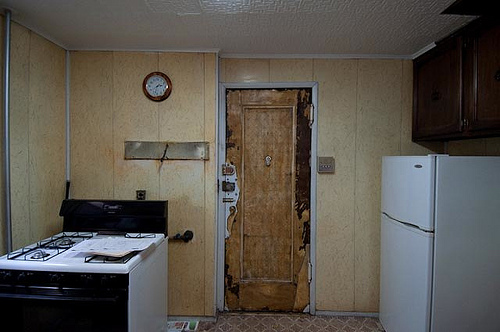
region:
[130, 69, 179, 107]
A clock on the wall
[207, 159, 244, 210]
Three locks on the door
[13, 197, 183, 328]
A stove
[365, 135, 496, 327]
A white refrigerator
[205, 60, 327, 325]
The door is damaged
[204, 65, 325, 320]
The door is brown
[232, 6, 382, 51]
The ceiling is tile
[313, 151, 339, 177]
An intercom panel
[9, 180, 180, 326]
Black and white stove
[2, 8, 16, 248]
A pipe along the wall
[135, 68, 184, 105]
A wooden clock on the wall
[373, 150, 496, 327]
A white refrigerator with 2 front doors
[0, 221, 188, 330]
A black and white stove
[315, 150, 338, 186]
A thermostat on the wall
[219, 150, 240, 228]
3 different door locks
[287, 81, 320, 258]
Discolored, fragmented door fram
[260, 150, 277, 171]
A peep hole in the door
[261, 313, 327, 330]
A beige designed tile floor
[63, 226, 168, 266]
Sheets of paper on the stove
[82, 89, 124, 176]
Light beige wall paneling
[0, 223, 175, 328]
Oven and range inside a kitchen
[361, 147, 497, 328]
Refrigerator with freezer inside a kitchen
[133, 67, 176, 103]
Clock hanging inside a kitchen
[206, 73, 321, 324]
Doorway to somebody's kitchen area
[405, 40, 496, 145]
Cupboards inside someone's kitchen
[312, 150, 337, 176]
Light switches inside a kitchen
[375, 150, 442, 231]
Freezer door on top section of a refrigerator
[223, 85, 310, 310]
Door needing repair in several places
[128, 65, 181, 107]
Round clock showing the local time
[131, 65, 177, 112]
Battery powered electric wall clock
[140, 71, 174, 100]
Clock on the wall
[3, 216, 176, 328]
Large cooker unit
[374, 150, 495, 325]
Two-door refrigerator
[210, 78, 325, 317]
Worn out closed door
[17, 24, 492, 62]
Clear white ceilling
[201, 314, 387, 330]
Plastic carpeted floor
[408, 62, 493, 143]
Overhead kitchen cabinets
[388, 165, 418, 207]
Clear white color on the regrigerator door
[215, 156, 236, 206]
Door latching and locking devices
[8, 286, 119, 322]
Black colored end of the cooker unit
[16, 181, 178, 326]
The stove is a gas stove.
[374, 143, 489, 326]
The refrigerator is white.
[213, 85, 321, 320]
A door is old.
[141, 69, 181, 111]
The clock face is white.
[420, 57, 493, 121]
The cupboards are brown.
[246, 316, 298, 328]
The floors are reddish pink.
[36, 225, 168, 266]
The stove top is white.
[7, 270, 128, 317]
The front of the oven is black.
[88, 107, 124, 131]
The wall color is light brown.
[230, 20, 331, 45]
The roof is white.